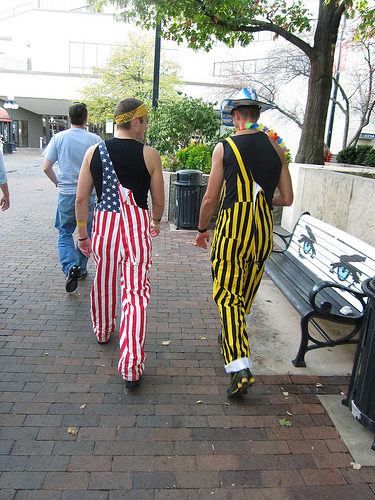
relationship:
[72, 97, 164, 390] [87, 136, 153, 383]
man wearing overalls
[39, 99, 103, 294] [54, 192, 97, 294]
man wearing jeans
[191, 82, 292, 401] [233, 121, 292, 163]
man wearing lei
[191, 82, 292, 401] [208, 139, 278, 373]
man wearing overalls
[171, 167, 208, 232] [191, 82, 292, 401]
trashcan in front of man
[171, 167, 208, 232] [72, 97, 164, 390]
trashcan in front of man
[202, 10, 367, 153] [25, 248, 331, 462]
tree beside sidewalk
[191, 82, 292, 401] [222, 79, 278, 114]
man wearing hat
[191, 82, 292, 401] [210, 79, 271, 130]
man has head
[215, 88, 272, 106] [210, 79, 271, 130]
hat on head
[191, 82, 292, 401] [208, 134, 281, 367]
man wearing clothes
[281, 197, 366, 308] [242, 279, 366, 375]
bench sitting on pavement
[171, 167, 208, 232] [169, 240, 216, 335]
trashcan sitting on pavement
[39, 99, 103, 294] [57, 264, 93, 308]
man wearing shoe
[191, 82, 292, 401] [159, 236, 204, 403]
man walking on sidewalk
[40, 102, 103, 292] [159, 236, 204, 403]
person walking on sidewalk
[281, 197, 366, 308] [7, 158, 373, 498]
bench on sidewalk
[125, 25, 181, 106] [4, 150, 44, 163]
lightpole across street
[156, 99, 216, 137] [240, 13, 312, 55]
green leaves on tree branch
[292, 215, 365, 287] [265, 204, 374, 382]
eyes on bench